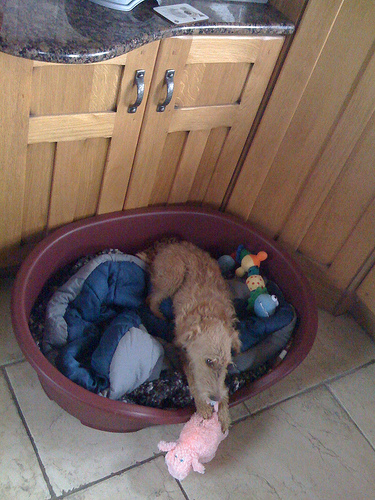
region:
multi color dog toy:
[223, 226, 284, 320]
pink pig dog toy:
[155, 399, 227, 498]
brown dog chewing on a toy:
[141, 235, 252, 499]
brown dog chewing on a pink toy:
[144, 233, 238, 491]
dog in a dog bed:
[14, 197, 328, 422]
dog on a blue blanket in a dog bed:
[12, 201, 339, 426]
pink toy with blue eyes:
[151, 400, 235, 493]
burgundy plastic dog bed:
[12, 206, 327, 436]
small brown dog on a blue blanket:
[120, 234, 242, 494]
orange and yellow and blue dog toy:
[230, 238, 283, 324]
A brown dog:
[147, 234, 237, 431]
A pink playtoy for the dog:
[154, 396, 228, 480]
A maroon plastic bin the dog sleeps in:
[8, 201, 320, 436]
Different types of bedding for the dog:
[31, 244, 184, 410]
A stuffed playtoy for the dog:
[229, 244, 279, 322]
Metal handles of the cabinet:
[126, 67, 177, 112]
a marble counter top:
[2, 1, 295, 64]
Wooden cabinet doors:
[0, 38, 290, 267]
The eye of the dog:
[202, 354, 218, 370]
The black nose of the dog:
[208, 392, 223, 401]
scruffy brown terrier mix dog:
[139, 234, 244, 432]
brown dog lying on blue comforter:
[57, 242, 238, 432]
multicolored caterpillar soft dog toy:
[230, 238, 280, 321]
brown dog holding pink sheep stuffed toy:
[142, 233, 241, 485]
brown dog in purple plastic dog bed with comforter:
[11, 202, 317, 479]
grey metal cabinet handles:
[124, 65, 178, 118]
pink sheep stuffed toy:
[155, 398, 231, 481]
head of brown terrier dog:
[181, 317, 242, 404]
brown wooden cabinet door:
[146, 36, 284, 215]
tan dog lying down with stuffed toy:
[139, 233, 244, 481]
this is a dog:
[130, 224, 276, 447]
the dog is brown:
[172, 314, 255, 376]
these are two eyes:
[153, 323, 243, 370]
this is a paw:
[182, 390, 263, 446]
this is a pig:
[162, 420, 222, 480]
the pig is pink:
[139, 422, 187, 462]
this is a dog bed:
[24, 289, 129, 405]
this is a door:
[49, 172, 103, 220]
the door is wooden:
[37, 185, 120, 315]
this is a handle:
[120, 111, 138, 114]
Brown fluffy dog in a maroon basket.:
[12, 203, 318, 433]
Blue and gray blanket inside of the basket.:
[44, 251, 295, 399]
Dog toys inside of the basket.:
[218, 247, 280, 318]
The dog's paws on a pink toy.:
[158, 398, 230, 482]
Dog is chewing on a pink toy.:
[158, 391, 230, 479]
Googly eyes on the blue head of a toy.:
[270, 292, 282, 308]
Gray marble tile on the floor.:
[0, 286, 374, 497]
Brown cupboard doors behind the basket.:
[0, 36, 291, 273]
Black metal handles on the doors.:
[124, 69, 177, 114]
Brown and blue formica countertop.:
[0, 0, 295, 64]